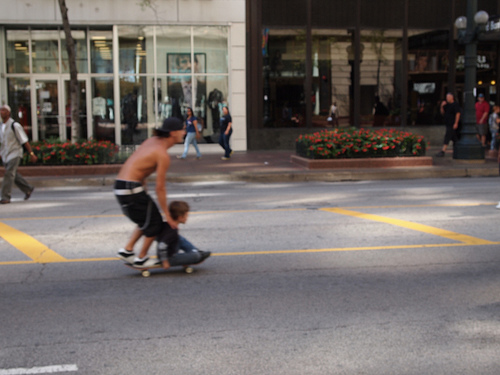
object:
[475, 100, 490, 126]
red shirt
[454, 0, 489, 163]
lamp post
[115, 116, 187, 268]
skater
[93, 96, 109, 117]
sign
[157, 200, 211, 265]
child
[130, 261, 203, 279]
skateboard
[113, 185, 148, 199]
white belt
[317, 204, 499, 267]
markings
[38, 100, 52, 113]
sign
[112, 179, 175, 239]
pants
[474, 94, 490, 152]
person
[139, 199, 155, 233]
chain